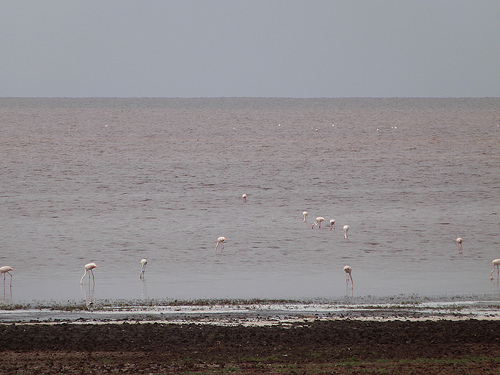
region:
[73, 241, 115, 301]
swan near a beach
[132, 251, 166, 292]
swan near a beach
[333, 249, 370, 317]
swan near a beach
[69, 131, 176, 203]
a clear body of water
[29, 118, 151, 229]
a body of water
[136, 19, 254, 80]
a clear blue sky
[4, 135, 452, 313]
birds in water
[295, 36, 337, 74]
white clouds in blue sky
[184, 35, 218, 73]
white clouds in blue sky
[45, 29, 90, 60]
white clouds in blue sky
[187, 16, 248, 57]
white clouds in blue sky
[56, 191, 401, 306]
these are wild birds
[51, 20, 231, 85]
the sky is hazy here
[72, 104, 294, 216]
this is the ocean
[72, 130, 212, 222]
the water is brown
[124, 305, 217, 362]
the ground here is sandy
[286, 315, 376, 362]
the ground here is rocky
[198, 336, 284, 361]
the ground here is dark brown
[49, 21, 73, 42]
white clouds in blue sky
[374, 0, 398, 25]
white clouds in blue sky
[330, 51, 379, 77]
white clouds in blue sky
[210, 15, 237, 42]
white clouds in blue sky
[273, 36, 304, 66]
white clouds in blue sky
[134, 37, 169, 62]
white clouds in blue sky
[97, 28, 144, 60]
white clouds in blue sky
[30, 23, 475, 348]
this along a coast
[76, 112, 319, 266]
this is an ocean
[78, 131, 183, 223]
the ocean is brown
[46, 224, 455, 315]
these are birds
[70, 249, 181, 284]
the birds are white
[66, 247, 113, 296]
the birds have long legs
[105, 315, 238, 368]
the ground here is dark brown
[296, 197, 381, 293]
the birds are standing in the water